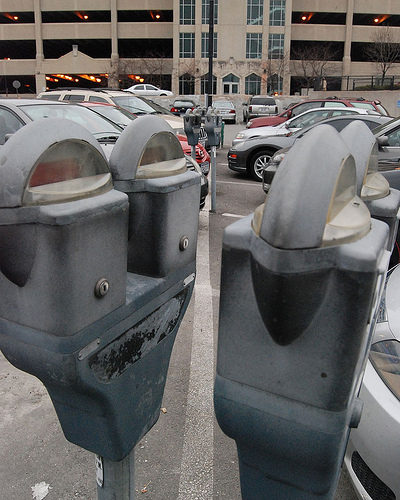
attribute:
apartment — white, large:
[161, 16, 309, 104]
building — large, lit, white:
[3, 0, 399, 116]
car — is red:
[73, 98, 211, 175]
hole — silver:
[94, 277, 111, 298]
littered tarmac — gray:
[0, 353, 388, 499]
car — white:
[231, 105, 383, 139]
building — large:
[0, 2, 399, 95]